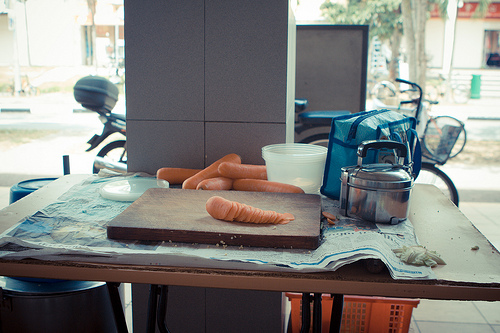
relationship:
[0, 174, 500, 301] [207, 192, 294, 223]
surface with carrot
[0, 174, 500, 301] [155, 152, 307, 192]
surface with carrot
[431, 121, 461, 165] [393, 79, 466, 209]
newspaper sitting in bicycle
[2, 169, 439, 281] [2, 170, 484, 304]
newspaper covering table top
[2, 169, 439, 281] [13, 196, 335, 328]
newspaper covering table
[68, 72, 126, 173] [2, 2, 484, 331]
bike parked outside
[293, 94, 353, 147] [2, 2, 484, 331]
bike parked outside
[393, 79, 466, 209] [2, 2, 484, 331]
bicycle parked outside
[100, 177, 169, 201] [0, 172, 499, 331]
lid lying on top of table